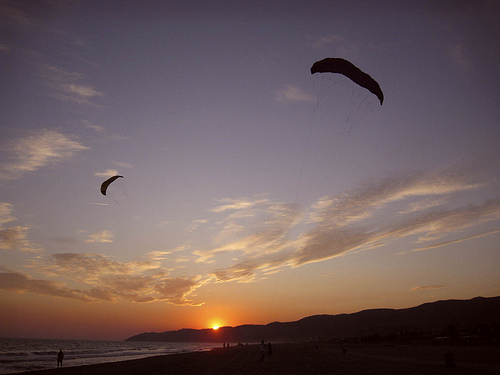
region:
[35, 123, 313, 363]
red sunsets on the beach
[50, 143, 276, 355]
parasailing at sunset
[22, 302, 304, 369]
beautiful beach sun set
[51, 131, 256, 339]
flying a kite at sun set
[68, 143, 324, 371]
flying a kite on the beach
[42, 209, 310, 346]
clouds and red sunset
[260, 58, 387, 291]
parachuting at sunset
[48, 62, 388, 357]
skydiving at sun set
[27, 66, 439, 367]
sky diving on to a beach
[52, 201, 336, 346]
blue skies, white clouds and red sunset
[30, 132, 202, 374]
flying a kite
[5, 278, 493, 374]
sunset at the ocean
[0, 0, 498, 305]
a few wispy clouds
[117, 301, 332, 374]
the sun in the west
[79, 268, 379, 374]
a colorful sunset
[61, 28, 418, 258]
two kites in the air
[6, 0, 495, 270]
light and dark sky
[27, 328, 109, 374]
a person on the beach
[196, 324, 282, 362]
people on the beach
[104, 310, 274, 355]
a small peninsula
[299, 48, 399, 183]
parasail with strings in sky.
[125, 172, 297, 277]
patch of cloudy sky.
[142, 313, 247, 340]
sun setting behind mountains.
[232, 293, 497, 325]
mountain range and sky.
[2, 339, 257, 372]
water with small waves.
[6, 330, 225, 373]
person standing by water.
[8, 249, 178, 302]
white clouds in sky.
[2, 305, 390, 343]
colors of the sun set.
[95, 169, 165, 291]
parasail in cloudy sky.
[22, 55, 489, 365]
two parasails at sunset.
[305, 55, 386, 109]
A large kit flying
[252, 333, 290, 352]
People flying the kite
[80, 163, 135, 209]
A kite flying in the distance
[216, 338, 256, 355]
People flying smaller kite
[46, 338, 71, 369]
A person standing on the shore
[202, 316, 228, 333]
The sun low in the sky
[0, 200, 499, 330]
A beautiful sunset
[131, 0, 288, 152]
A blue evening sky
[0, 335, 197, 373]
Person standing in front of a body of water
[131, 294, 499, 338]
Hills in the background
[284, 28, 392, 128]
a black parachute on air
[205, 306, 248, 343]
a sun setting on the scene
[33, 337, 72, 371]
a man standing next to water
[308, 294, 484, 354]
a dark mountain on the scene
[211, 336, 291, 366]
people walking on the sea shore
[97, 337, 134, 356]
waves in the sea shore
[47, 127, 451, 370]
a dark scene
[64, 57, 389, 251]
two parachute on air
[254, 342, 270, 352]
a man with white vest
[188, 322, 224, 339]
a sun seting on the background